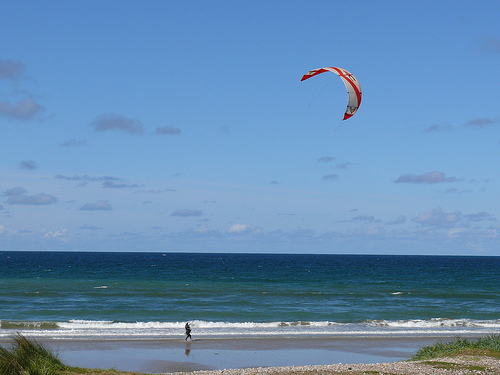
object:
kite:
[299, 67, 363, 121]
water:
[0, 251, 500, 337]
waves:
[0, 315, 499, 341]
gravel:
[382, 366, 385, 367]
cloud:
[151, 126, 183, 136]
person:
[184, 322, 194, 343]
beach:
[0, 331, 499, 373]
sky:
[0, 0, 498, 256]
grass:
[0, 331, 145, 375]